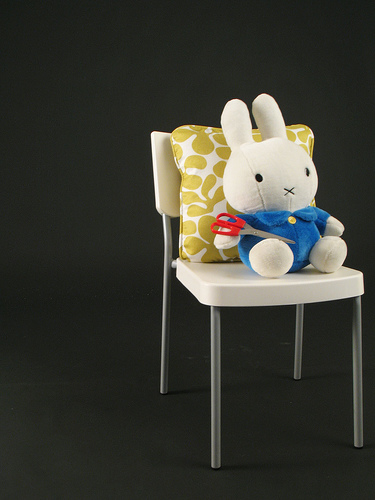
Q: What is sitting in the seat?
A: Toy rabbit.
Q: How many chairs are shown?
A: One.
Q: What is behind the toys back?
A: Pillow.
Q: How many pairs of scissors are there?
A: One.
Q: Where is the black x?
A: Toys nose.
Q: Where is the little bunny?
A: Sitting on the chair.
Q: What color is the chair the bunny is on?
A: White.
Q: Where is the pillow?
A: Behind the bunny.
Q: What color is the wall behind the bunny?
A: Black.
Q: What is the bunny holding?
A: Scissors.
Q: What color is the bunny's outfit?
A: Blue.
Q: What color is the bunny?
A: White.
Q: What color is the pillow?
A: Gold and white.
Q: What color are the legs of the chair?
A: Silver.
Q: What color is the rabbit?
A: White.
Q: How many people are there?
A: None.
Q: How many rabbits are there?
A: One.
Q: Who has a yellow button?
A: The rabbit.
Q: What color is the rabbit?
A: White.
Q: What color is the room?
A: Black.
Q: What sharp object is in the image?
A: Scissors.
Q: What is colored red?
A: Scissor handles.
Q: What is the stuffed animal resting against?
A: Pillow.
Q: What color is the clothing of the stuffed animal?
A: Blue.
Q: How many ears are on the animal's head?
A: Two.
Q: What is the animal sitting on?
A: Chair.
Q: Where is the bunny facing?
A: Forward.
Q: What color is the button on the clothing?
A: Yellow.